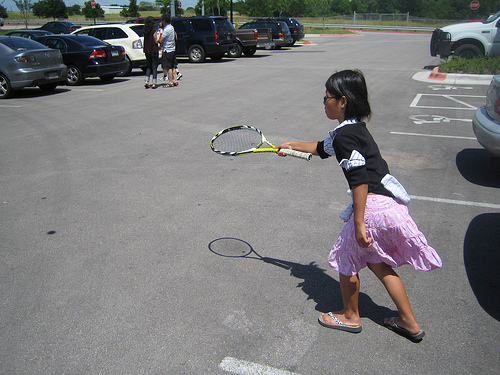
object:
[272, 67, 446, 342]
girl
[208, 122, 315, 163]
tennis racket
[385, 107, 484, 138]
parking space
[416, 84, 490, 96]
parking space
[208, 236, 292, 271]
shadow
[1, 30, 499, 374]
pavement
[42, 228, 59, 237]
shadow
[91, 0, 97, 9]
stop sign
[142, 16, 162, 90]
person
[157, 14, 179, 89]
person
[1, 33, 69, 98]
car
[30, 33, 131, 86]
car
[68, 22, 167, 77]
car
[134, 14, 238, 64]
car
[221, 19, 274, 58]
car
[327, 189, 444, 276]
skirt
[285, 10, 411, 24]
fence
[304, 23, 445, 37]
street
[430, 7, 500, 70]
truck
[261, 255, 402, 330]
shadow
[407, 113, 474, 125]
handicapped sign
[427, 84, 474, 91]
handicapped sign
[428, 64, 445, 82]
curb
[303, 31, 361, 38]
curb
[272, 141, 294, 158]
hand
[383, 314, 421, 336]
right foot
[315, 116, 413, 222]
shirt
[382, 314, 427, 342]
flip flop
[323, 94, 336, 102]
glasses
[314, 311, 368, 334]
flip flop